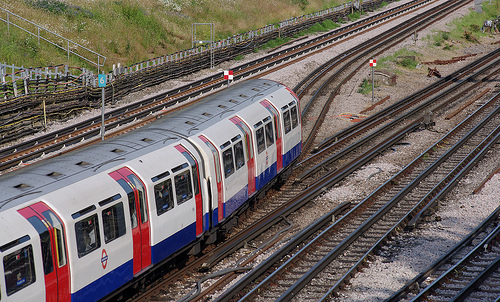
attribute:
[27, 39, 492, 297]
tracks — red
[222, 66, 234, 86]
sign — red, white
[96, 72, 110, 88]
blue sign — small blue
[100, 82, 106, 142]
metal pole — metal 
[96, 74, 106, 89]
signs — blue 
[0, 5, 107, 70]
fence — grey 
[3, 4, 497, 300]
tracks — empty, train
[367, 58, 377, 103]
sign — red , white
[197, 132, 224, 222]
door — Two red 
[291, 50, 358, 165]
tracks — train, split 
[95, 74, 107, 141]
sign — tall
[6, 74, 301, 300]
train — red white , blue, side 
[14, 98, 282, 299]
doors — red 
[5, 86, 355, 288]
train — side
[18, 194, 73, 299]
doors — red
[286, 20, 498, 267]
tracks — empty train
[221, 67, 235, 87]
sign — white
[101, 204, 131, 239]
windows — side